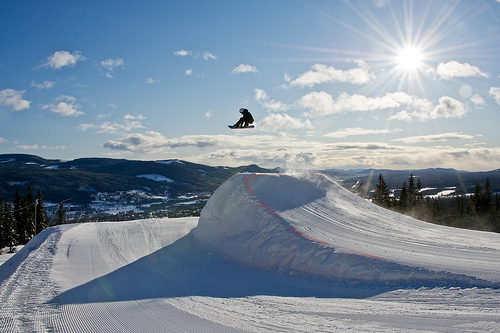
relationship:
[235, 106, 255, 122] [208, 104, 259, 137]
man doing tricks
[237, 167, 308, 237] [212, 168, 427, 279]
line on top of snow hill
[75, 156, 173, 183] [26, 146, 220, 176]
mountains in background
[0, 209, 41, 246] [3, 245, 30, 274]
trees on side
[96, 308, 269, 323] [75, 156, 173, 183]
snow on top of mountains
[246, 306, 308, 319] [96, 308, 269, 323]
prints on top of snow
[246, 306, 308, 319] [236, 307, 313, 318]
prints of tires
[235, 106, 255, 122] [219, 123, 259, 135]
person on top of snowboard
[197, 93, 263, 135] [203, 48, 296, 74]
snowboarder jumping in air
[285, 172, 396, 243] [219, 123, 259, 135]
slope for snowboarding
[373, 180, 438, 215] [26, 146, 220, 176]
pine trees in background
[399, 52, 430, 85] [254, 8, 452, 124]
sun inside of sky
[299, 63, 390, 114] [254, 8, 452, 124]
clouds inside of sky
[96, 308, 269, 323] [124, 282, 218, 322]
snow on top of ground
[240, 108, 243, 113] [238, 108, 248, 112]
helmet on top of head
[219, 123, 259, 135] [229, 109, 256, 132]
snowboard for riding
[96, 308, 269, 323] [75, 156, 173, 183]
snow covers mountains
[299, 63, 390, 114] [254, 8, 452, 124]
clouds in sky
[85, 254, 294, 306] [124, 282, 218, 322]
shadow on top of ground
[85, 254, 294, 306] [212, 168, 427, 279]
shadow from snow hill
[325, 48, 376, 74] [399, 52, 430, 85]
rays from sun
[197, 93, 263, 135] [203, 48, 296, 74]
snowboarder inside of air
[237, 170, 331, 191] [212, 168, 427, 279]
ramp made of snow hill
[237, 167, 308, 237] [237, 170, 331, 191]
line on perimeter of ramp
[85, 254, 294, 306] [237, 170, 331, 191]
shadow cast by ramp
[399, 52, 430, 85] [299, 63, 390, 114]
sun above clouds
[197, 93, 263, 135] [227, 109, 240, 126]
snowboarder facing front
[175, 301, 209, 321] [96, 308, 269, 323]
patches of snow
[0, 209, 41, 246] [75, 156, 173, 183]
trees in front of mountains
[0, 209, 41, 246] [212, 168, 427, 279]
trees in front of snow hill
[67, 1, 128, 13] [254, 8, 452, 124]
part of sky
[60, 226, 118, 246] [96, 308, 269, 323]
part of snow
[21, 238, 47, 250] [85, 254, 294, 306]
edge of shadow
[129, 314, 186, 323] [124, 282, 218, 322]
part of ground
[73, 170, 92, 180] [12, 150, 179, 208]
part of hills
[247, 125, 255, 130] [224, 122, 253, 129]
part of board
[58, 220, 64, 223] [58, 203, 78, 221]
part of post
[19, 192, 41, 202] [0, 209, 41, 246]
part of trees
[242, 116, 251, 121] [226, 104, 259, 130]
part of jumper